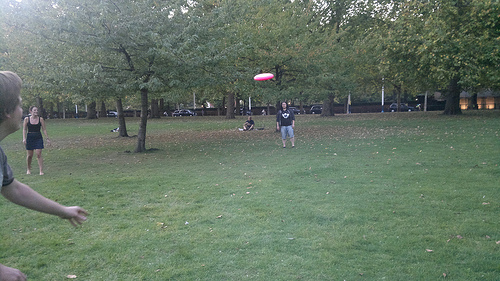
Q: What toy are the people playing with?
A: Frisbee.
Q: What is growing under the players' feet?
A: Grass.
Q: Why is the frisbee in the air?
A: It was thrown.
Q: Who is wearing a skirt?
A: Woman walking on left.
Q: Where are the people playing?
A: In a park.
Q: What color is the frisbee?
A: Orange.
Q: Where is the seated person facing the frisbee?
A: In the middle.